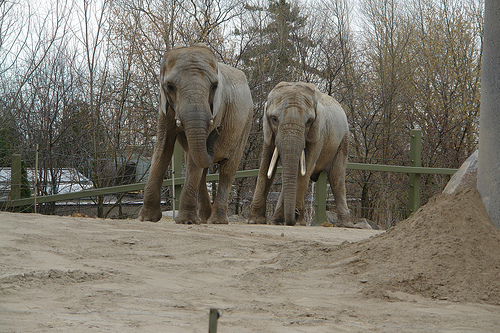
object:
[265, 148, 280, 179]
elephant tusk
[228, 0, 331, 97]
pine tree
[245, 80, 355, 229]
elephant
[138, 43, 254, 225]
elephant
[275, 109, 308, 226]
trunk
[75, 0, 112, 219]
tree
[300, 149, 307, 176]
elephant tusks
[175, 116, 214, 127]
elephant tusks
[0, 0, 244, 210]
branches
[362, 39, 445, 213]
benches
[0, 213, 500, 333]
sandy area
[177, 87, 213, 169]
elephant trunk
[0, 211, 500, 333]
ground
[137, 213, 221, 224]
toe nails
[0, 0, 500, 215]
background trees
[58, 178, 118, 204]
exhibit fencing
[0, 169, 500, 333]
sand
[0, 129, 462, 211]
fence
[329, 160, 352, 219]
leg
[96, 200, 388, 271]
incline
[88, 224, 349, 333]
trail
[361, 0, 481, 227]
tree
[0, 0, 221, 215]
outside